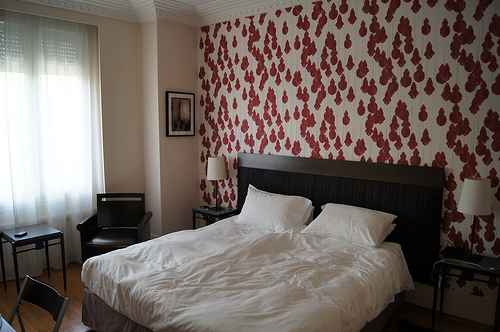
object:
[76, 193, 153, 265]
chair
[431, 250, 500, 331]
nightstand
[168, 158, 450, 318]
bag sentence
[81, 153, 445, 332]
bed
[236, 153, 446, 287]
headboard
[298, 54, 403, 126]
red dots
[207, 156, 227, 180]
lamp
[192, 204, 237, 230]
night stand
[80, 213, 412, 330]
white spread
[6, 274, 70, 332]
desk chair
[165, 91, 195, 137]
art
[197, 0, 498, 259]
wallpaper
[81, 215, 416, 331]
sheets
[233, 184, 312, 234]
pillow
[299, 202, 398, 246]
pillow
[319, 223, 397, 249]
pillow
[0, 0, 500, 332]
room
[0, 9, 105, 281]
curtains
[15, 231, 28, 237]
remote control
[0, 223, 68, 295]
small table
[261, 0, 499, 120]
wall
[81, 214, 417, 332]
spread